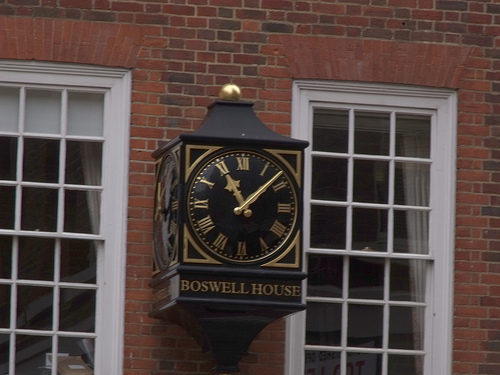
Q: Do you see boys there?
A: No, there are no boys.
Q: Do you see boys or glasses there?
A: No, there are no boys or glasses.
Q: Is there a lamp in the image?
A: No, there are no lamps.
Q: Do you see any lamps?
A: No, there are no lamps.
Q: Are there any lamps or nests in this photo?
A: No, there are no lamps or nests.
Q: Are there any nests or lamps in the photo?
A: No, there are no lamps or nests.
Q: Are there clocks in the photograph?
A: Yes, there is a clock.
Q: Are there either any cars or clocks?
A: Yes, there is a clock.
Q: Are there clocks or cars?
A: Yes, there is a clock.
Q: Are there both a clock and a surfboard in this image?
A: No, there is a clock but no surfboards.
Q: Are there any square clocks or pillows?
A: Yes, there is a square clock.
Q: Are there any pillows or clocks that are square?
A: Yes, the clock is square.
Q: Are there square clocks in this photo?
A: Yes, there is a square clock.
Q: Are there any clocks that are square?
A: Yes, there is a clock that is square.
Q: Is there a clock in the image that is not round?
A: Yes, there is a square clock.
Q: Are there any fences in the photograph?
A: No, there are no fences.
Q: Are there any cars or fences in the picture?
A: No, there are no fences or cars.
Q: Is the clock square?
A: Yes, the clock is square.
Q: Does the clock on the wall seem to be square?
A: Yes, the clock is square.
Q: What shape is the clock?
A: The clock is square.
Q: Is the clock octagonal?
A: No, the clock is square.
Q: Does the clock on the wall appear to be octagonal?
A: No, the clock is square.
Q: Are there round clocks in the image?
A: No, there is a clock but it is square.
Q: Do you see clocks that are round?
A: No, there is a clock but it is square.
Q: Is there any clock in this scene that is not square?
A: No, there is a clock but it is square.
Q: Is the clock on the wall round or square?
A: The clock is square.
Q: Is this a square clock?
A: Yes, this is a square clock.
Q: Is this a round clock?
A: No, this is a square clock.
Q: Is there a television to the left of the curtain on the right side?
A: No, there is a clock to the left of the curtain.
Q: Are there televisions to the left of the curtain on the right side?
A: No, there is a clock to the left of the curtain.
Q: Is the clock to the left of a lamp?
A: No, the clock is to the left of the curtain.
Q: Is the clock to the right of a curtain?
A: No, the clock is to the left of a curtain.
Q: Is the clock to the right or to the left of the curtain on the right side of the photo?
A: The clock is to the left of the curtain.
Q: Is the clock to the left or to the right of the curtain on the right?
A: The clock is to the left of the curtain.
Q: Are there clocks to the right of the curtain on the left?
A: Yes, there is a clock to the right of the curtain.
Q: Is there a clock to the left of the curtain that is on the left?
A: No, the clock is to the right of the curtain.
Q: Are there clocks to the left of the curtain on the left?
A: No, the clock is to the right of the curtain.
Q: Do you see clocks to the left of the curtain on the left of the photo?
A: No, the clock is to the right of the curtain.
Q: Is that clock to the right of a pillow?
A: No, the clock is to the right of a curtain.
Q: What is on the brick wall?
A: The clock is on the wall.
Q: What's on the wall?
A: The clock is on the wall.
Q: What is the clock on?
A: The clock is on the wall.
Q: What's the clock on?
A: The clock is on the wall.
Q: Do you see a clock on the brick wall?
A: Yes, there is a clock on the wall.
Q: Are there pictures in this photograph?
A: No, there are no pictures.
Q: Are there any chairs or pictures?
A: No, there are no pictures or chairs.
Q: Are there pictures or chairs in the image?
A: No, there are no pictures or chairs.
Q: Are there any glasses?
A: No, there are no glasses.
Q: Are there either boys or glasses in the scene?
A: No, there are no glasses or boys.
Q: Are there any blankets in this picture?
A: No, there are no blankets.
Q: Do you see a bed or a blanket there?
A: No, there are no blankets or beds.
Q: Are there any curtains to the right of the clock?
A: Yes, there is a curtain to the right of the clock.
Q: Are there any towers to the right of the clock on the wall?
A: No, there is a curtain to the right of the clock.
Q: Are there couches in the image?
A: No, there are no couches.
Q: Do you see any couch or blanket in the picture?
A: No, there are no couches or blankets.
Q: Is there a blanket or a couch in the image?
A: No, there are no couches or blankets.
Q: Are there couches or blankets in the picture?
A: No, there are no couches or blankets.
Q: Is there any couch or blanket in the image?
A: No, there are no couches or blankets.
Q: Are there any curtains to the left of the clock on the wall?
A: Yes, there is a curtain to the left of the clock.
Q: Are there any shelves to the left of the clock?
A: No, there is a curtain to the left of the clock.